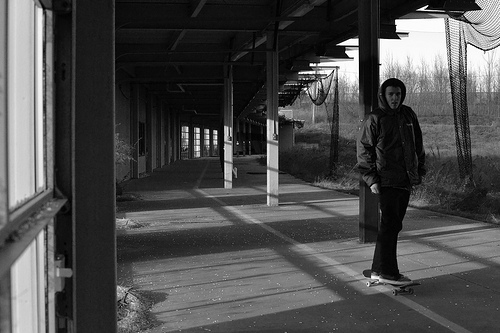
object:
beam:
[223, 63, 234, 189]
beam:
[356, 11, 381, 244]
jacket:
[355, 77, 426, 190]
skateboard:
[361, 269, 422, 296]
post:
[266, 39, 279, 207]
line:
[191, 189, 430, 321]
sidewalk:
[126, 197, 499, 321]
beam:
[266, 2, 280, 207]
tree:
[379, 51, 498, 117]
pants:
[370, 176, 412, 281]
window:
[180, 125, 189, 159]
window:
[192, 126, 201, 158]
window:
[202, 127, 211, 157]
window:
[211, 129, 219, 157]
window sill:
[0, 188, 67, 273]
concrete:
[114, 160, 500, 333]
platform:
[114, 151, 500, 332]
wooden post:
[223, 58, 233, 189]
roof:
[116, 0, 485, 131]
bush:
[114, 122, 142, 165]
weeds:
[423, 140, 497, 210]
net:
[442, 1, 499, 184]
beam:
[69, 0, 119, 333]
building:
[1, 0, 485, 333]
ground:
[116, 157, 500, 332]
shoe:
[378, 274, 414, 286]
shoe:
[370, 269, 405, 280]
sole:
[378, 280, 413, 288]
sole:
[370, 274, 378, 279]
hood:
[377, 78, 406, 116]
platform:
[15, 0, 487, 130]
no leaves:
[114, 123, 133, 197]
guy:
[353, 77, 428, 286]